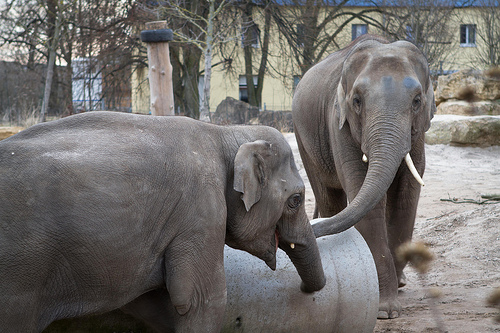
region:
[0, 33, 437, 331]
the elephants in the enclosure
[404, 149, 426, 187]
the long tusk on the elephant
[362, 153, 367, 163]
the short tusk on the elephant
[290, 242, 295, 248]
the short tusk on the elephant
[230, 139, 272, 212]
the ear on the elephant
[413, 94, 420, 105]
the eye on the elephant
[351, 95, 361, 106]
the eye on the elephant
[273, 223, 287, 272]
the mouth on the elephant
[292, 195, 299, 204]
the eye on the elephant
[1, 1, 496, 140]
the bare trees behind the elephants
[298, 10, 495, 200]
a big greu elephant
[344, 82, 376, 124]
the eye of a elephant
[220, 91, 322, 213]
the ear of a elephant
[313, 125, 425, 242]
the trunk of a elephant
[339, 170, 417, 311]
the front leg of a elephant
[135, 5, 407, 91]
trees with no leaves on it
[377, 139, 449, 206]
the whit tusk on a elephant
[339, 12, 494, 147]
the head of a elephant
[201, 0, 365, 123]
a house in the background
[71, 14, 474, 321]
two big grey elephants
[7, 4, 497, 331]
two elephants in a pen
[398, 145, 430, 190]
a white tusk of elephant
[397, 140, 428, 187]
tusk is curved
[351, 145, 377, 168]
tusk on left is short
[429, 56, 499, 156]
stones in a pen of elephants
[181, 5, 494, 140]
a yellow building behind elephants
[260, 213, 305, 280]
mouth of elephant is open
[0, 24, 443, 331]
elephants are next a tube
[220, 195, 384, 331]
a tube of cement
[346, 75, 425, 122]
eyes of elephant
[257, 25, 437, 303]
the elephant is gray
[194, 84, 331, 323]
the elephant is smiling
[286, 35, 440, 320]
elephant has tusks and is gray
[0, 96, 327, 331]
elephant has tusks and is gray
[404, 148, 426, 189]
ivory tusk on elephant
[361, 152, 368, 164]
ivory tusk on elephant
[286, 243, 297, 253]
ivory tusk on elephant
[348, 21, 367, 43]
window on yellow house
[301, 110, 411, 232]
gray trunk on elephant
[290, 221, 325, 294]
gray trunk on elephant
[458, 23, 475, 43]
window on yellow house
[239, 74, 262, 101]
window on yellow house